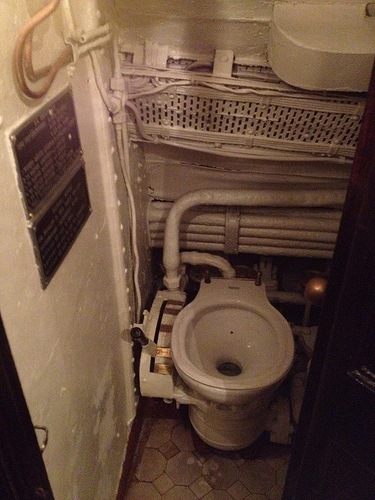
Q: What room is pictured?
A: It is a bathroom.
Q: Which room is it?
A: It is a bathroom.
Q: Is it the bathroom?
A: Yes, it is the bathroom.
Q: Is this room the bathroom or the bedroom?
A: It is the bathroom.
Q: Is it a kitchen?
A: No, it is a bathroom.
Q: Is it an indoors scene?
A: Yes, it is indoors.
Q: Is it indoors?
A: Yes, it is indoors.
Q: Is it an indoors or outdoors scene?
A: It is indoors.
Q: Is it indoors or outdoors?
A: It is indoors.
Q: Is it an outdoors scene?
A: No, it is indoors.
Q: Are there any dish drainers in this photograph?
A: No, there are no dish drainers.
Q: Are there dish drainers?
A: No, there are no dish drainers.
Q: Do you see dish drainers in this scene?
A: No, there are no dish drainers.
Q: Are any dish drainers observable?
A: No, there are no dish drainers.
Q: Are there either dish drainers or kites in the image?
A: No, there are no dish drainers or kites.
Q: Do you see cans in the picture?
A: No, there are no cans.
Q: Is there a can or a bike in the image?
A: No, there are no cans or bikes.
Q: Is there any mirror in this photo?
A: No, there are no mirrors.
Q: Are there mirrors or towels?
A: No, there are no mirrors or towels.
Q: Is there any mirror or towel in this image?
A: No, there are no mirrors or towels.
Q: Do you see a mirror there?
A: No, there are no mirrors.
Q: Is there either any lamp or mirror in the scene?
A: No, there are no mirrors or lamps.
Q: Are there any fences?
A: No, there are no fences.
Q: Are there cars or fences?
A: No, there are no fences or cars.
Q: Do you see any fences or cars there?
A: No, there are no fences or cars.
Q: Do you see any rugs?
A: No, there are no rugs.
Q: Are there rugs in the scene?
A: No, there are no rugs.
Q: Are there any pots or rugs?
A: No, there are no rugs or pots.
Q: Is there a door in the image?
A: Yes, there is a door.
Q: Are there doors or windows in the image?
A: Yes, there is a door.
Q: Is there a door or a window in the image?
A: Yes, there is a door.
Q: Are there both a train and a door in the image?
A: No, there is a door but no trains.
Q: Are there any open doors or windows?
A: Yes, there is an open door.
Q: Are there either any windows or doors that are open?
A: Yes, the door is open.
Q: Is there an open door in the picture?
A: Yes, there is an open door.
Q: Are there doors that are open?
A: Yes, there is a door that is open.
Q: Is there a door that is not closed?
A: Yes, there is a open door.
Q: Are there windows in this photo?
A: No, there are no windows.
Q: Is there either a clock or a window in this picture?
A: No, there are no windows or clocks.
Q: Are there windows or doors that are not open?
A: No, there is a door but it is open.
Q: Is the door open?
A: Yes, the door is open.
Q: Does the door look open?
A: Yes, the door is open.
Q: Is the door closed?
A: No, the door is open.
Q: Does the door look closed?
A: No, the door is open.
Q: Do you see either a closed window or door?
A: No, there is a door but it is open.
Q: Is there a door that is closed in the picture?
A: No, there is a door but it is open.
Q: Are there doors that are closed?
A: No, there is a door but it is open.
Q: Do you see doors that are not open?
A: No, there is a door but it is open.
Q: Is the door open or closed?
A: The door is open.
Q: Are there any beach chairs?
A: No, there are no beach chairs.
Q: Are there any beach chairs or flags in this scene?
A: No, there are no beach chairs or flags.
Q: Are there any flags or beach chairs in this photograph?
A: No, there are no beach chairs or flags.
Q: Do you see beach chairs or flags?
A: No, there are no beach chairs or flags.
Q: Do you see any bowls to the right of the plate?
A: Yes, there is a bowl to the right of the plate.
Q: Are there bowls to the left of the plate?
A: No, the bowl is to the right of the plate.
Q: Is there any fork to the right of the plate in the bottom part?
A: No, there is a bowl to the right of the plate.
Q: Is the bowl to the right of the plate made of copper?
A: Yes, the bowl is to the right of the plate.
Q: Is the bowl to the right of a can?
A: No, the bowl is to the right of the plate.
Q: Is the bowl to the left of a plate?
A: No, the bowl is to the right of a plate.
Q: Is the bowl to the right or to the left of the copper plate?
A: The bowl is to the right of the plate.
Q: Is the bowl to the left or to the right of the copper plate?
A: The bowl is to the right of the plate.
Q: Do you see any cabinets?
A: No, there are no cabinets.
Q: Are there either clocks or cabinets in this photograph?
A: No, there are no cabinets or clocks.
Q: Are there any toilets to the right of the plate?
A: Yes, there is a toilet to the right of the plate.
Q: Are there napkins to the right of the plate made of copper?
A: No, there is a toilet to the right of the plate.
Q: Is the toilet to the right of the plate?
A: Yes, the toilet is to the right of the plate.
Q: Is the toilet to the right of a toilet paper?
A: No, the toilet is to the right of the plate.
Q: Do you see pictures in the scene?
A: No, there are no pictures.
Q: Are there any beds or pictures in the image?
A: No, there are no pictures or beds.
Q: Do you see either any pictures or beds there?
A: No, there are no pictures or beds.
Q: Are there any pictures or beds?
A: No, there are no pictures or beds.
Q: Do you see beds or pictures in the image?
A: No, there are no pictures or beds.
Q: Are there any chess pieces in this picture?
A: No, there are no chess pieces.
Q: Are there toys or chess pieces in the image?
A: No, there are no chess pieces or toys.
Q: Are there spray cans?
A: No, there are no spray cans.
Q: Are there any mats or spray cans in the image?
A: No, there are no spray cans or mats.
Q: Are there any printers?
A: No, there are no printers.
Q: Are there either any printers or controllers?
A: No, there are no printers or controllers.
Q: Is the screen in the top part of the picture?
A: Yes, the screen is in the top of the image.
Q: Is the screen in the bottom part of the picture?
A: No, the screen is in the top of the image.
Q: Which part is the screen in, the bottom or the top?
A: The screen is in the top of the image.